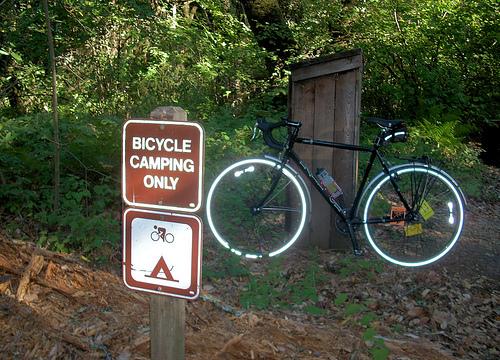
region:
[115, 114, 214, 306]
two red and white warning signs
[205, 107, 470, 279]
black bike with white tires parked against wooden structure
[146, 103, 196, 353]
wooden post holding signs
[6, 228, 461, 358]
wooded ground area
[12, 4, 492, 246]
background of trees and green grass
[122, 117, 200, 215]
sign indicating bicycle only camping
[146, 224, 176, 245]
small red figure of cyclist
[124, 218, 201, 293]
white sign trimmed in red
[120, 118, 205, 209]
red sign trimmed in white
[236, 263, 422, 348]
ivy growing on forest floor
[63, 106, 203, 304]
This is a street sign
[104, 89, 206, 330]
This is a sign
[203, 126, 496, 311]
This is a bike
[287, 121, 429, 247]
The bike is large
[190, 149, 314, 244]
This is a wheel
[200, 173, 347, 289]
The wheel is metal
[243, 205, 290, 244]
The spikes are metal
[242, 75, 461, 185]
This is a small barn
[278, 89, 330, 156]
This is made of wood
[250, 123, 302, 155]
This is a handle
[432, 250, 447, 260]
the back tire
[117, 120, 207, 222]
a sign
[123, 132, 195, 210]
the letters are white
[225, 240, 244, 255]
the front tire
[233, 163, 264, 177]
a reflector on the bike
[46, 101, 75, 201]
a tree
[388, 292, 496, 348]
leaves on the floor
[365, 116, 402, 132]
the seat on the bike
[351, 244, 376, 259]
the pedal on the bike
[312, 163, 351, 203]
the water bottle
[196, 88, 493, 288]
a black bike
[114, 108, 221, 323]
two brown and white signs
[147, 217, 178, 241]
a bike on one sign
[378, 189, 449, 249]
yellow and orange cards in spokes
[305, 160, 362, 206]
a water bottle on bike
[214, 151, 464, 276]
white wheels on bike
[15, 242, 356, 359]
wood chips on the ground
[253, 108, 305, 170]
black curved handle bars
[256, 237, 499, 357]
man brown dead leaves on ground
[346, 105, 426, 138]
a black seat on bike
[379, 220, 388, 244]
part of a wheel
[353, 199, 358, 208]
part of a peddle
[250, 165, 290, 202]
edge of a wheel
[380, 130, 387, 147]
edge of a seat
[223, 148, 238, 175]
part of a bush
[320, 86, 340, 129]
part of a block